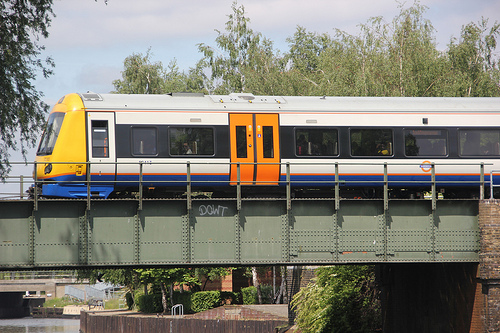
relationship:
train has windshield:
[23, 87, 500, 198] [32, 109, 70, 158]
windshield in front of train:
[32, 109, 70, 158] [23, 87, 500, 198]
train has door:
[23, 87, 500, 198] [224, 111, 284, 190]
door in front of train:
[224, 111, 284, 190] [23, 87, 500, 198]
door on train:
[224, 111, 284, 190] [23, 87, 500, 198]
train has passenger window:
[23, 87, 500, 198] [166, 126, 217, 159]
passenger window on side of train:
[166, 126, 217, 159] [23, 87, 500, 198]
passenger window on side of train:
[293, 125, 344, 159] [23, 87, 500, 198]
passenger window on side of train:
[348, 126, 397, 159] [23, 87, 500, 198]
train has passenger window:
[23, 87, 500, 198] [348, 126, 397, 159]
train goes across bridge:
[23, 87, 500, 198] [2, 159, 500, 275]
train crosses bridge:
[23, 87, 500, 198] [2, 159, 500, 275]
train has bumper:
[23, 87, 500, 198] [32, 179, 118, 201]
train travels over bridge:
[23, 87, 500, 198] [2, 159, 500, 275]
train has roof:
[23, 87, 500, 198] [76, 88, 500, 111]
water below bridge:
[1, 310, 84, 332] [2, 159, 500, 275]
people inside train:
[178, 132, 498, 153] [23, 87, 500, 198]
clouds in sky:
[27, 3, 499, 59] [2, 0, 499, 198]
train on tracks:
[23, 87, 500, 198] [1, 191, 498, 203]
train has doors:
[23, 87, 500, 198] [224, 111, 284, 190]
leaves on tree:
[92, 269, 236, 288] [155, 283, 179, 318]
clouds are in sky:
[27, 3, 499, 59] [2, 0, 499, 198]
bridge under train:
[2, 159, 500, 275] [23, 87, 500, 198]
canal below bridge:
[1, 287, 127, 331] [2, 159, 500, 275]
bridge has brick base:
[2, 159, 500, 275] [459, 195, 498, 331]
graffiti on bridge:
[192, 200, 233, 221] [2, 159, 500, 275]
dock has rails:
[80, 297, 296, 320] [167, 299, 187, 315]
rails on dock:
[167, 299, 187, 315] [80, 297, 296, 320]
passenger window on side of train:
[402, 127, 451, 160] [23, 87, 500, 198]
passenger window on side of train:
[456, 127, 500, 159] [23, 87, 500, 198]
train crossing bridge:
[23, 87, 500, 198] [2, 159, 500, 275]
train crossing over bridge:
[23, 87, 500, 198] [2, 159, 500, 275]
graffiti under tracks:
[192, 200, 233, 221] [1, 191, 498, 203]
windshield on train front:
[32, 109, 70, 158] [28, 90, 92, 182]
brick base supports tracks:
[459, 195, 498, 331] [1, 191, 498, 203]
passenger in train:
[177, 138, 196, 157] [23, 87, 500, 198]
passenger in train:
[374, 138, 391, 157] [23, 87, 500, 198]